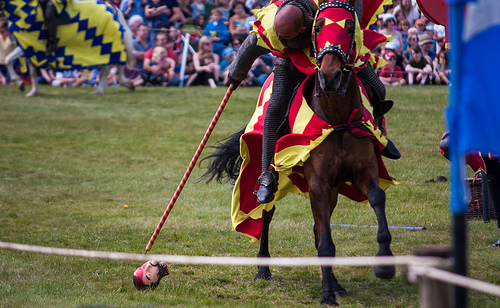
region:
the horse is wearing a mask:
[302, 3, 373, 116]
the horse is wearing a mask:
[273, 5, 388, 156]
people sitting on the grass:
[101, 20, 236, 90]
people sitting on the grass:
[370, 7, 455, 94]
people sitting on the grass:
[117, 13, 317, 105]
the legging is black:
[238, 49, 300, 239]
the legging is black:
[227, 53, 338, 277]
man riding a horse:
[234, 5, 421, 235]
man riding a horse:
[247, 15, 371, 184]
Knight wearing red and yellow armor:
[226, 6, 413, 203]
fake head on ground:
[132, 255, 171, 290]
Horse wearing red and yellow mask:
[312, 5, 356, 96]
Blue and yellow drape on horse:
[3, 0, 135, 90]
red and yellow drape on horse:
[232, 67, 400, 235]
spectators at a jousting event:
[37, 0, 452, 86]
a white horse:
[0, 0, 127, 96]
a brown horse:
[261, 2, 396, 297]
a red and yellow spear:
[148, 85, 229, 251]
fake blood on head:
[133, 264, 149, 280]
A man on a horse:
[211, 3, 421, 306]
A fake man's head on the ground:
[119, 248, 176, 307]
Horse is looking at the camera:
[303, 3, 372, 95]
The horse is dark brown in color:
[254, 1, 427, 302]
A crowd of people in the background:
[3, 0, 446, 92]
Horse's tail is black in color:
[195, 107, 266, 202]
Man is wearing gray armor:
[214, 0, 406, 211]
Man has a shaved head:
[266, 3, 310, 54]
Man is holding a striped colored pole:
[103, 70, 248, 257]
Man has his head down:
[262, 0, 315, 47]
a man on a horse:
[194, 6, 465, 235]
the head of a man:
[241, 0, 332, 82]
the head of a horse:
[281, 5, 416, 122]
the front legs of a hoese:
[292, 159, 441, 301]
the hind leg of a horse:
[232, 161, 328, 290]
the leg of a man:
[243, 68, 300, 205]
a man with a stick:
[104, 9, 377, 278]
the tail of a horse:
[200, 83, 272, 205]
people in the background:
[46, 0, 321, 82]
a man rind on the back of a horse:
[188, 4, 456, 261]